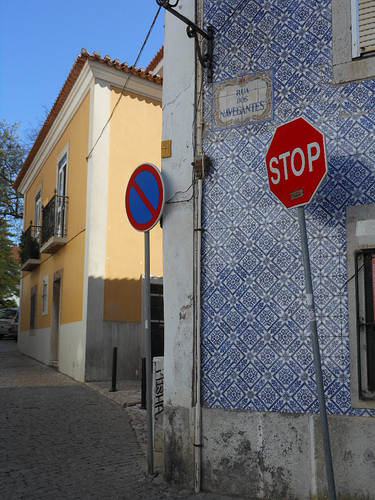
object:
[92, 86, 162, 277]
wall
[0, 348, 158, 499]
street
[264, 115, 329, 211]
sign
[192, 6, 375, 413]
wall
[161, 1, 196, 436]
wall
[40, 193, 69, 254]
terrace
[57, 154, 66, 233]
window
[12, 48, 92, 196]
gutter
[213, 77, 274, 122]
sign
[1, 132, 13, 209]
leaves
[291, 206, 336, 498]
pole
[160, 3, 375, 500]
building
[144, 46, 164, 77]
roof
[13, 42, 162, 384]
building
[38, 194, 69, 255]
balcony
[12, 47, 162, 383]
house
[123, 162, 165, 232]
sign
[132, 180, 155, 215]
diagonal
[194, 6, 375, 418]
tiles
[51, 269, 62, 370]
doorway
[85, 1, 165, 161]
power line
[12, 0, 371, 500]
buildings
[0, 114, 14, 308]
tree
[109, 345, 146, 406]
poles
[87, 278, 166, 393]
alley